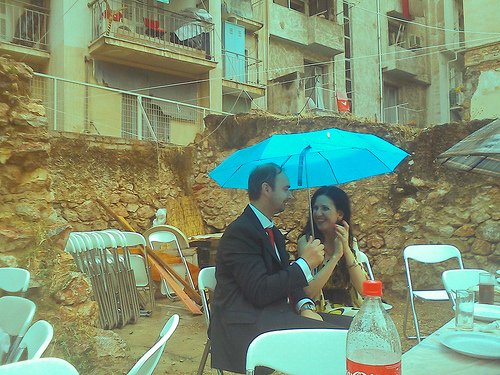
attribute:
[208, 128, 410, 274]
umbrella — light blue, blue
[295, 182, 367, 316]
woman — smiling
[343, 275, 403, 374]
bottle — plastic, coke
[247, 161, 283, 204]
hair — short, dark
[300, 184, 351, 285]
hair — dark, long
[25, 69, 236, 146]
fence — white, chain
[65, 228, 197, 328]
chairs — in a row, metal, white, folding, folded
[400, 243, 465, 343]
folding chair — white, empty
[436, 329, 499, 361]
plate — white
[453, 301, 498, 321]
plate — white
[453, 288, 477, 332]
glass — empty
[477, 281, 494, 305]
liquid — brown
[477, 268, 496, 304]
glass — almost full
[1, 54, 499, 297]
wall — rock